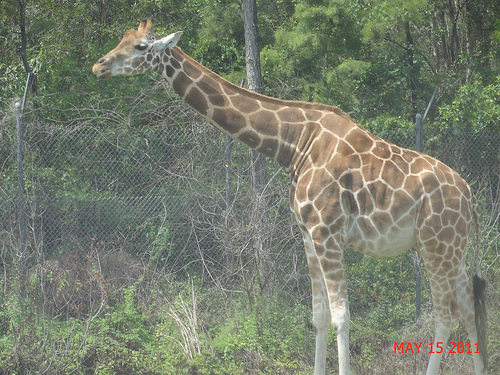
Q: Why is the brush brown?
A: The brush is is dead.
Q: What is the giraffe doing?
A: Standing.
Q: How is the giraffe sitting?
A: Its not sitting it's standing.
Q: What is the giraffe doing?
A: Standing.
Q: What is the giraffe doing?
A: Standing.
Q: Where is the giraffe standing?
A: Next to grass.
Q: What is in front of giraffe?
A: Fence.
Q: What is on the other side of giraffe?
A: Trees.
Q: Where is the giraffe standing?
A: Around trees.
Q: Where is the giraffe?
A: The giraffe is in the forest.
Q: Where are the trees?
A: Behind the giraffe.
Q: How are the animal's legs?
A: There are standing.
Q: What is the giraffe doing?
A: The giraffe is standing.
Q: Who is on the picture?
A: A giraffe.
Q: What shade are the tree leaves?
A: The tree leaves are green color.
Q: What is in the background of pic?
A: Fence on the right side of the giraffe.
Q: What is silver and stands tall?
A: A metal fence post.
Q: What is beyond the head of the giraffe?
A: Green trees behind the metal fence.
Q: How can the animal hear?
A: The giraffe has ears.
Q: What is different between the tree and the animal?
A: The giraffe has ears.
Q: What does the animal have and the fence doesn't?
A: The giraffe has ears.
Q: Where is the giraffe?
A: In a forest.